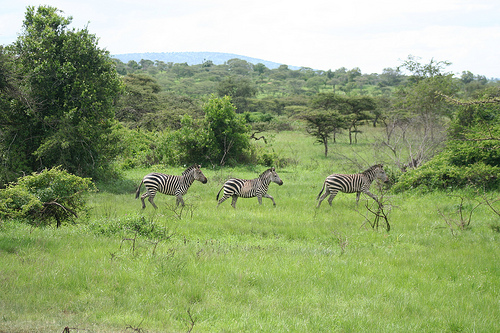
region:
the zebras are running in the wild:
[137, 152, 404, 225]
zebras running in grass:
[130, 155, 402, 216]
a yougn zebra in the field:
[211, 167, 296, 214]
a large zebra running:
[131, 157, 211, 214]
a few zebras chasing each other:
[131, 151, 402, 219]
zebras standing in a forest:
[132, 81, 400, 216]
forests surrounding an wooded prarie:
[2, 21, 456, 159]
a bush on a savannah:
[4, 165, 105, 237]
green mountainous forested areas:
[112, 41, 289, 93]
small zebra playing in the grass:
[212, 164, 286, 218]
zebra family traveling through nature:
[131, 155, 398, 215]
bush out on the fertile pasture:
[2, 167, 91, 229]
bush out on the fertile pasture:
[175, 96, 257, 171]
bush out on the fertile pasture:
[397, 157, 498, 196]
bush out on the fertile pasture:
[452, 99, 493, 144]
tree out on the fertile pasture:
[296, 102, 346, 153]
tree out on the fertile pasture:
[17, 4, 102, 166]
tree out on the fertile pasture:
[337, 92, 375, 149]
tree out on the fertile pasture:
[402, 67, 435, 136]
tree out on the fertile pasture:
[217, 73, 256, 124]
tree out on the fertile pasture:
[121, 73, 161, 133]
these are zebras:
[86, 90, 457, 318]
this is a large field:
[80, 75, 411, 303]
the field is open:
[86, 88, 334, 281]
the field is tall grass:
[86, 215, 370, 316]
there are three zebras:
[77, 132, 481, 268]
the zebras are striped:
[76, 126, 373, 209]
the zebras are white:
[135, 136, 398, 241]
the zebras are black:
[147, 157, 362, 247]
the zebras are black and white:
[120, 147, 480, 257]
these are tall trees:
[26, 47, 111, 198]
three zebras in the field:
[126, 151, 397, 225]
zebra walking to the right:
[311, 159, 397, 215]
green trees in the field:
[3, 0, 497, 332]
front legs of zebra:
[253, 189, 280, 210]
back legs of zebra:
[213, 191, 240, 208]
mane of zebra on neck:
[177, 157, 197, 174]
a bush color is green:
[394, 126, 499, 202]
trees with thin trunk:
[290, 80, 381, 163]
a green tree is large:
[1, 4, 129, 176]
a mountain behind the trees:
[108, 44, 313, 82]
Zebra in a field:
[126, 155, 211, 217]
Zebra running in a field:
[216, 155, 289, 216]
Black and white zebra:
[309, 147, 386, 218]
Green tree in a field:
[6, 161, 94, 240]